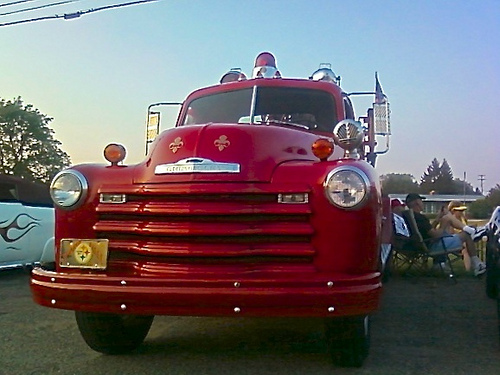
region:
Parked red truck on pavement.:
[28, 49, 395, 360]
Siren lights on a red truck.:
[181, 41, 341, 82]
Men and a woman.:
[386, 181, 481, 278]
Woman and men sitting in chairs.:
[394, 190, 489, 286]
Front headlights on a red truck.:
[45, 160, 375, 220]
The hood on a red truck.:
[125, 120, 335, 180]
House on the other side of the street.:
[380, 190, 485, 215]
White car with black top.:
[0, 170, 55, 265]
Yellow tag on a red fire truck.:
[55, 230, 115, 270]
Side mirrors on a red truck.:
[135, 90, 390, 160]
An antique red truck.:
[43, 18, 395, 351]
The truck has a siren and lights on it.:
[90, 30, 370, 170]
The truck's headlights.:
[45, 160, 375, 220]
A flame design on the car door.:
[0, 200, 55, 275]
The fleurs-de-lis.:
[155, 125, 231, 157]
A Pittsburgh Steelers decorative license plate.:
[45, 232, 115, 272]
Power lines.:
[0, 0, 146, 32]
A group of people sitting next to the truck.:
[332, 45, 497, 295]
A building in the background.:
[390, 185, 485, 215]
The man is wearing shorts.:
[397, 190, 480, 276]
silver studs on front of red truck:
[217, 304, 338, 330]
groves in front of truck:
[96, 185, 328, 280]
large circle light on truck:
[306, 159, 369, 218]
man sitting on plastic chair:
[405, 183, 441, 252]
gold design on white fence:
[8, 213, 43, 241]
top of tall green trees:
[410, 151, 456, 183]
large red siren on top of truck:
[235, 44, 292, 94]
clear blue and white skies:
[54, 39, 162, 95]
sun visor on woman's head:
[447, 199, 473, 219]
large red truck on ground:
[40, 29, 440, 324]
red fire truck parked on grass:
[28, 37, 412, 366]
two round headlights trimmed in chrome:
[43, 160, 371, 212]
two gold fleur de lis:
[167, 135, 237, 155]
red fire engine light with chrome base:
[243, 49, 283, 84]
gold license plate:
[58, 237, 113, 272]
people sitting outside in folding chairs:
[386, 188, 498, 294]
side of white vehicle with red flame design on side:
[1, 175, 61, 272]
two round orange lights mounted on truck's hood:
[98, 134, 337, 166]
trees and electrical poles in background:
[378, 160, 498, 195]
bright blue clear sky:
[5, 0, 499, 185]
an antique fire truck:
[32, 49, 395, 354]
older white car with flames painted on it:
[0, 175, 52, 273]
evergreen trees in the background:
[418, 156, 475, 195]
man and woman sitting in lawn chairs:
[403, 192, 490, 274]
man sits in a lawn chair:
[389, 197, 410, 268]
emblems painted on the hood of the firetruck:
[167, 133, 237, 152]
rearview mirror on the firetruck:
[146, 101, 185, 142]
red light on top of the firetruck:
[252, 51, 279, 76]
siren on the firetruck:
[331, 117, 368, 159]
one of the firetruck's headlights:
[321, 163, 376, 208]